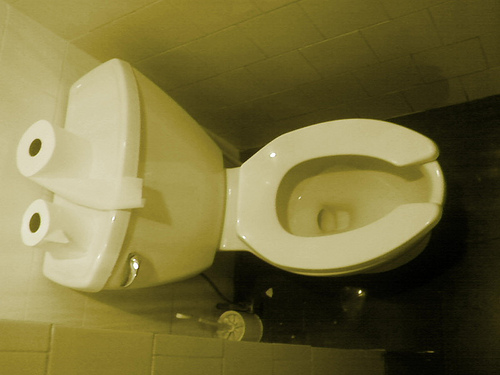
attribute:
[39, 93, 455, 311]
toilet — white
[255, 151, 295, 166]
glare — light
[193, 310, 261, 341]
brush — toilet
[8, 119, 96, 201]
paper — toilet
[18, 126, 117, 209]
paper — toilet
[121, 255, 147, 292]
handle — silver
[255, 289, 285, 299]
paper — toilet, small, piece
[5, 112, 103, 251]
paper — toilet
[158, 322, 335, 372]
wall — brick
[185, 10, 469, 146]
wall — brick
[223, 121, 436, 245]
seat — TOILET, DOWN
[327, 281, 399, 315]
glare — LIGHT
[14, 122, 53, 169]
roll — LARGE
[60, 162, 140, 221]
paper — TOILET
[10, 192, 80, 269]
paper — TOILET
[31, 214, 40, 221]
roll — SMALL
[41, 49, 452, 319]
toilet — white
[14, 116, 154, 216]
toilet paper — full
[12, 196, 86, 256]
toilet paper — full, smaller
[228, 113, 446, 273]
toilet seat — white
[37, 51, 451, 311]
toilet bowl — white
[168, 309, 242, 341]
toilet brush — white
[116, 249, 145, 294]
toilet handle — silver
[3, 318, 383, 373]
wall — brick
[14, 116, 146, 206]
roll — TOILET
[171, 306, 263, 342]
brush — TOILET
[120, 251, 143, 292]
handle — CHROME